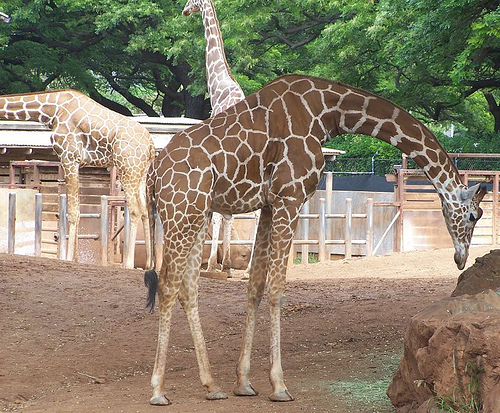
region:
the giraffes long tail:
[143, 173, 158, 318]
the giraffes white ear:
[456, 183, 479, 200]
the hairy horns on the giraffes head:
[470, 184, 490, 204]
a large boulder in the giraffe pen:
[388, 267, 499, 412]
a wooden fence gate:
[376, 165, 436, 255]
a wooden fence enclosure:
[303, 197, 398, 264]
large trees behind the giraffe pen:
[1, 0, 182, 93]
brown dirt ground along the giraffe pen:
[1, 260, 147, 412]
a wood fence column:
[32, 192, 43, 256]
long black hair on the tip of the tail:
[143, 267, 159, 312]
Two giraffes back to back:
[50, 114, 324, 182]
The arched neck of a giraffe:
[380, 107, 400, 138]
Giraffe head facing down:
[442, 187, 477, 259]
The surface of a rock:
[434, 304, 499, 361]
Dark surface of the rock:
[477, 263, 499, 285]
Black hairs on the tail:
[145, 278, 156, 292]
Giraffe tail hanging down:
[147, 189, 152, 239]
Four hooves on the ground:
[148, 389, 293, 404]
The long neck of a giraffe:
[205, 22, 218, 78]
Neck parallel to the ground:
[2, 97, 52, 119]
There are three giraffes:
[8, 8, 473, 375]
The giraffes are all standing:
[14, 15, 471, 400]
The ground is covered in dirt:
[7, 253, 129, 410]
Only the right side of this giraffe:
[156, 76, 465, 388]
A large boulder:
[374, 275, 496, 410]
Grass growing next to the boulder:
[413, 373, 485, 412]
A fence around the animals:
[320, 167, 432, 252]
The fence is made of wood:
[321, 172, 431, 251]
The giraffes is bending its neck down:
[351, 98, 496, 265]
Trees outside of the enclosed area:
[11, 4, 498, 129]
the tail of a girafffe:
[144, 185, 158, 311]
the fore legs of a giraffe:
[230, 215, 330, 408]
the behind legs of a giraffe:
[155, 236, 226, 407]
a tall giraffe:
[145, 66, 450, 408]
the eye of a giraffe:
[465, 206, 480, 221]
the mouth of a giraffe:
[450, 250, 475, 270]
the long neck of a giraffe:
[328, 80, 465, 190]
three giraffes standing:
[25, 43, 495, 408]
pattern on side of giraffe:
[224, 109, 295, 176]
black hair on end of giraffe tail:
[139, 269, 164, 316]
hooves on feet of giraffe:
[143, 374, 296, 410]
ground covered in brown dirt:
[7, 267, 129, 372]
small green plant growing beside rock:
[437, 374, 487, 411]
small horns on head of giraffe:
[458, 181, 493, 205]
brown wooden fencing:
[314, 198, 379, 263]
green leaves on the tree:
[442, 80, 483, 128]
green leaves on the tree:
[417, 11, 433, 40]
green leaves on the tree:
[480, 13, 499, 33]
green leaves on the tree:
[372, 38, 397, 60]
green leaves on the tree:
[267, 18, 318, 52]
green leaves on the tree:
[224, 24, 270, 64]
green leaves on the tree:
[122, 15, 154, 46]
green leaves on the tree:
[172, 34, 190, 64]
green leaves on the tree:
[35, 38, 108, 89]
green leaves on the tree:
[72, 29, 150, 84]